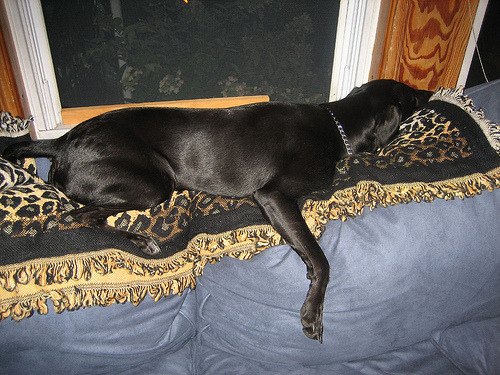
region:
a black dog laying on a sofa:
[31, 73, 467, 335]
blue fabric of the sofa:
[44, 293, 471, 357]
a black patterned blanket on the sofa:
[0, 128, 470, 300]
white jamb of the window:
[0, 20, 80, 131]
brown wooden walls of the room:
[404, 3, 464, 86]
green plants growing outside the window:
[59, 10, 307, 87]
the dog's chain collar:
[312, 88, 369, 177]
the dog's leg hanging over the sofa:
[241, 183, 355, 358]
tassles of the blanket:
[1, 276, 224, 310]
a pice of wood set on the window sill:
[38, 87, 275, 129]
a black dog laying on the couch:
[0, 70, 442, 341]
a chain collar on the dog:
[318, 98, 361, 158]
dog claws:
[312, 324, 329, 346]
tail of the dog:
[5, 119, 72, 174]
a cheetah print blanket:
[5, 82, 489, 326]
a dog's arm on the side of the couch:
[256, 193, 331, 348]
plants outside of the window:
[42, 3, 354, 110]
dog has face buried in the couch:
[357, 75, 443, 140]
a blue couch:
[2, 193, 498, 373]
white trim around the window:
[5, 4, 383, 121]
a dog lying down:
[8, 78, 436, 341]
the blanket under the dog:
[1, 85, 497, 314]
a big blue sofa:
[20, 79, 493, 374]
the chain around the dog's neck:
[322, 103, 354, 156]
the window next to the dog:
[8, 0, 380, 111]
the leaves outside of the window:
[63, 9, 332, 98]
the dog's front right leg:
[255, 172, 332, 343]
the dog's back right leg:
[66, 163, 164, 251]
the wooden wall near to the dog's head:
[391, 2, 463, 89]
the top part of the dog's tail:
[2, 131, 55, 165]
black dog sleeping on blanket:
[7, 85, 429, 340]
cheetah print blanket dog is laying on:
[0, 110, 499, 295]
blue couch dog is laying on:
[6, 142, 488, 374]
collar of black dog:
[321, 98, 356, 158]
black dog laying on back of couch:
[2, 82, 460, 343]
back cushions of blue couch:
[12, 176, 489, 366]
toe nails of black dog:
[303, 318, 328, 345]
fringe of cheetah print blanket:
[6, 80, 497, 332]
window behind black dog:
[6, 8, 357, 126]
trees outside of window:
[46, 2, 306, 102]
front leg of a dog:
[253, 166, 341, 346]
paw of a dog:
[299, 285, 326, 343]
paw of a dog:
[127, 225, 167, 260]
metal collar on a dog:
[325, 96, 360, 167]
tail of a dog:
[0, 128, 60, 171]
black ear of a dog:
[369, 100, 405, 152]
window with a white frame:
[4, 3, 390, 136]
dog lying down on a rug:
[0, 67, 486, 339]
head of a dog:
[319, 67, 451, 160]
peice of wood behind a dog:
[54, 90, 275, 137]